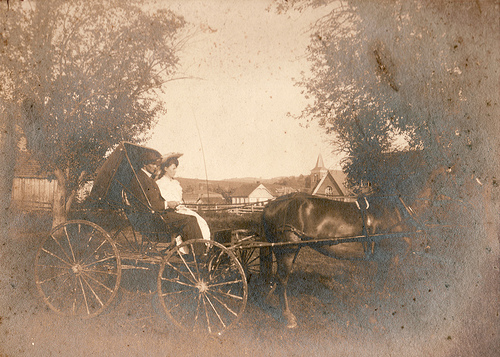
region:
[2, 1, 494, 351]
THE PHOTO IS RATHER OLD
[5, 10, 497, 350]
THE PHOTO IS DAMAGED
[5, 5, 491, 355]
THE PHOTO IS FADED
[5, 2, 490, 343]
THE PHOTO IS WORN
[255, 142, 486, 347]
THIS IS A HORSE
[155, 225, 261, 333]
THIS IS A WAGON WHEEL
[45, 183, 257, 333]
THIS IS A CART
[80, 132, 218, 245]
THE MAN AND WOMAN ARE SITTING TOGETHER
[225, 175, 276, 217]
THE BUILDING IS WHITE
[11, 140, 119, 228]
THE BARN IS IN THE BACKGROUND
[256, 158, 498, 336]
A horse in the foreground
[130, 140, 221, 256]
Two people in the foreground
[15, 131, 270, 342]
A wagon in the foreground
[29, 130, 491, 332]
A horse is pulling the wagon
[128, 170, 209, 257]
Man is wearing a dark suit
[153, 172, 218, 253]
Woman is wearing a white dress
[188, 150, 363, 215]
Buildings in the background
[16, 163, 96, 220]
A fence in the background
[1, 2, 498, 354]
Photo was taken in the daytime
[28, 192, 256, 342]
Bottom of the wagon is made of wood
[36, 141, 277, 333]
A horse drawn buggy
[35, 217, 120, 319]
A large rear wheel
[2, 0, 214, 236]
Tree in the background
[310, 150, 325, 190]
Spire of a building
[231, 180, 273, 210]
The building is white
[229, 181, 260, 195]
The roof is dark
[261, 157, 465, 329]
A horse is standing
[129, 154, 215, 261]
A man is driving the buggy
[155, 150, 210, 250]
Woman sitting in the buggy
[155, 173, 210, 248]
The dress is white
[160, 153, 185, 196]
The woman's dress is white.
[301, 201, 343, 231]
The horse is brown.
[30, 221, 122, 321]
The wheel is round.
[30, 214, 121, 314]
The wheel is made from wood.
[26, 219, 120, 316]
The wheel is brown is color.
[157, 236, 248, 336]
The front wheel is round.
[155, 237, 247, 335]
The front wheel is made from wood.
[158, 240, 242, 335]
The front wheel is brown is color.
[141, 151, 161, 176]
The man is wearing a hat.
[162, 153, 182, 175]
The woman is wearing a hat.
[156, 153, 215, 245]
Woman in a horse and buggy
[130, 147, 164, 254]
Man in a horse and buggy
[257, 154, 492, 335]
Black horse pulling buggy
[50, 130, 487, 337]
Man and woman riding in horse and buggy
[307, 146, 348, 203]
Church with steeple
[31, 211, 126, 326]
Wagon wheel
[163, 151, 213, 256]
Woman in white dress with hat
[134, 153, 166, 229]
man in black suit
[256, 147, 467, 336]
Black horse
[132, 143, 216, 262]
man in black suit and woman in white dress